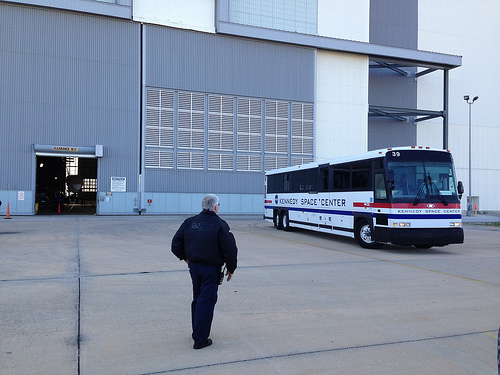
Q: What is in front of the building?
A: A bus.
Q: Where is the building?
A: Behind the bus.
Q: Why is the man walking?
A: To go to the bus.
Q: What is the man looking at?
A: The bus.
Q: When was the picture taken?
A: Daytime.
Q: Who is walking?
A: The man.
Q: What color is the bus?
A: Black and white.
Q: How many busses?
A: 1.